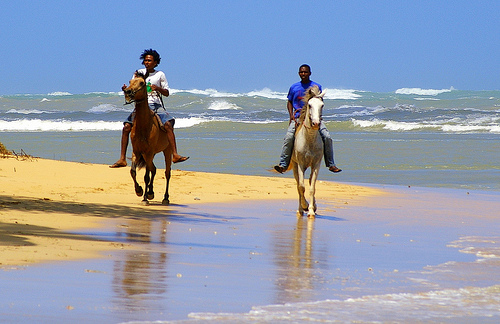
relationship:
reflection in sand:
[289, 208, 315, 280] [1, 151, 499, 321]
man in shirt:
[275, 63, 341, 173] [284, 80, 320, 114]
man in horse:
[275, 63, 341, 173] [290, 88, 324, 218]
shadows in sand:
[1, 191, 255, 258] [4, 152, 366, 249]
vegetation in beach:
[0, 142, 29, 156] [4, 88, 496, 321]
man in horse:
[275, 63, 341, 173] [72, 26, 222, 192]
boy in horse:
[108, 48, 191, 167] [280, 88, 331, 219]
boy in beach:
[108, 48, 191, 167] [1, 139, 406, 320]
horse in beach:
[283, 81, 328, 223] [14, 89, 450, 309]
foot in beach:
[109, 156, 129, 168] [1, 148, 386, 270]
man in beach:
[275, 63, 341, 173] [4, 88, 496, 321]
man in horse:
[275, 63, 341, 173] [120, 67, 172, 207]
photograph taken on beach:
[2, 1, 484, 320] [25, 150, 364, 270]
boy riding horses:
[108, 48, 191, 167] [116, 71, 329, 224]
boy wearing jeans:
[108, 48, 192, 167] [123, 102, 174, 126]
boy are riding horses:
[108, 48, 191, 167] [115, 79, 192, 209]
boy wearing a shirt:
[108, 48, 191, 167] [138, 63, 176, 123]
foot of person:
[109, 156, 129, 168] [109, 47, 190, 168]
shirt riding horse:
[262, 69, 342, 119] [294, 86, 329, 218]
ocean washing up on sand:
[1, 85, 500, 188] [36, 226, 228, 280]